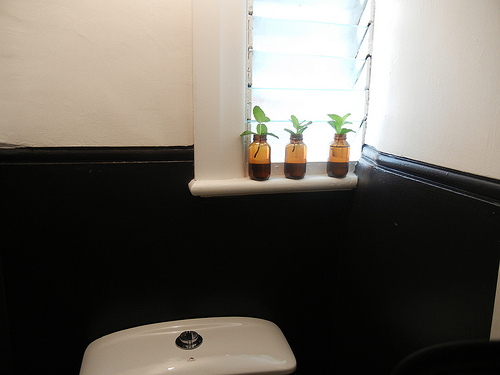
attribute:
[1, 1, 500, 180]
wall — grey, clean, unwritten, white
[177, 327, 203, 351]
metal — shiny, small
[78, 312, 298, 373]
surface — white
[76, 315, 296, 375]
toilet — clean, white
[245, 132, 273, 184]
jar — small, brown, half-filled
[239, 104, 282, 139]
plant — green, growing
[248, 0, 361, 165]
window — open, clean, blind-like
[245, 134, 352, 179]
jars — identical, planters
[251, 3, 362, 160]
window panes — glass, open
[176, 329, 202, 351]
toilet flush — silver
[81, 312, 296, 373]
toilet tank lit — white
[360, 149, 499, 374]
right wall — black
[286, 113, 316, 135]
plant — green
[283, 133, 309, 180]
jar — brown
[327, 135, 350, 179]
jar — brown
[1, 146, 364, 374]
left wall — black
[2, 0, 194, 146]
left wall — white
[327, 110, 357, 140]
right plant — green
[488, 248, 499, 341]
object — white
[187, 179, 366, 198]
window sill — white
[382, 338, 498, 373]
object — black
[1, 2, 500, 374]
bathroom — partially black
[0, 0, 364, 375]
wall — black, white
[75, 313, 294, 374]
top — white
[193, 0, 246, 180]
moulding — white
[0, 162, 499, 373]
wall — black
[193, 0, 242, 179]
frame — white